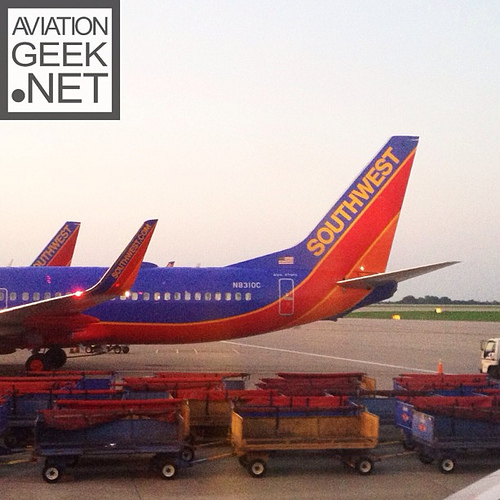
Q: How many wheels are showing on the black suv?
A: There is two.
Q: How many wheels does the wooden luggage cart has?
A: It is four.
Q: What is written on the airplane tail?
A: Southwest.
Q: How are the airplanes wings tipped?
A: Upwards.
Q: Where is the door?
A: On the back of the airplane.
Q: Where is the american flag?
A: On the airplane.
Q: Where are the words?
A: On the wings and the airplane.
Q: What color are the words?
A: Yellow.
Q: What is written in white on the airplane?
A: White.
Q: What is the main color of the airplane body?
A: Blue.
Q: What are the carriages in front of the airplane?
A: They are baggage carriers.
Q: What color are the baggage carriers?
A: Blue, yellow, and red.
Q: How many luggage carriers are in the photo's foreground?
A: 3.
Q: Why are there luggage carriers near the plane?
A: To load luggage.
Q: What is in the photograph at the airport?
A: An airplane.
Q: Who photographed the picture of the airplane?
A: An employee.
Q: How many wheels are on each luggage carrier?
A: 4.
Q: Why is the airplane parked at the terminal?
A: To load passengers.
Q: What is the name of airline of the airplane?
A: Southwest.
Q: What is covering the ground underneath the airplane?
A: Asphalt.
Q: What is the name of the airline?
A: Southwest.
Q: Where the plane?
A: On the runway.